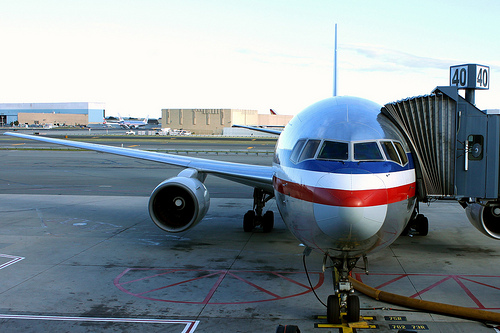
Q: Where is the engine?
A: On the wing.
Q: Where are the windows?
A: On the front of the plane.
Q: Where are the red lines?
A: On the tarmac.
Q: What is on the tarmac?
A: Red lines.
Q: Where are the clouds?
A: In the sky.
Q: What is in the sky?
A: Clouds.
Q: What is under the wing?
A: The engine.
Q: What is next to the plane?
A: The jetway.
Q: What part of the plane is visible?
A: Front.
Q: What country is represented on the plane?
A: USA.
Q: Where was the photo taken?
A: At an airport.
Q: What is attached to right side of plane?
A: Transporter.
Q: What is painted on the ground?
A: Red and white lines.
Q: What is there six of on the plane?
A: Front windows.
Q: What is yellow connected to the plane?
A: Hose.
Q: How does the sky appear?
A: Cloudy.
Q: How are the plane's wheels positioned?
A: Down.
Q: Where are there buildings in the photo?
A: In the distance.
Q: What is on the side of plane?
A: Loader.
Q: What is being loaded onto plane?
A: Human beings.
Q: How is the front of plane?
A: Needle nose.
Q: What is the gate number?
A: 40.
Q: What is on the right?
A: Gate.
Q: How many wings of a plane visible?
A: One.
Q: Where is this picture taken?
A: Airport.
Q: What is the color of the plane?
A: White.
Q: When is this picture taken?
A: Day time.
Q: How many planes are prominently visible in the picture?
A: One.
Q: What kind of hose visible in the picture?
A: Fuel hose.